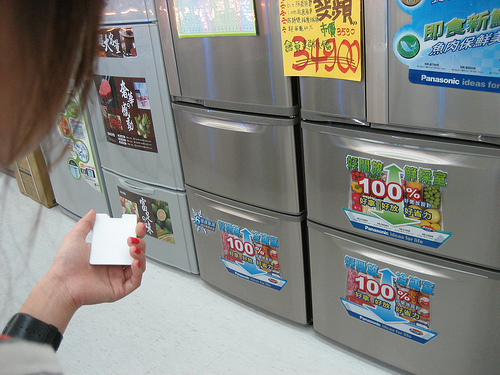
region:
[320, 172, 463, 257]
sign on the door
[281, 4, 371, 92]
red lettering on the sign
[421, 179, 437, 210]
grapes in the picture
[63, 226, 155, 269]
girl with phone in hand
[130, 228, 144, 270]
nail polish on fingernails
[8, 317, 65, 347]
black wrist band on wrist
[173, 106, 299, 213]
front of shelf is gray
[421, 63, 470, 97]
make of appliance on sign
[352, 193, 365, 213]
tomatoes on the advertisment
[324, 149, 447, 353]
two signs on each shelf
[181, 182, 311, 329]
a brushed aluminum refrigerator drawer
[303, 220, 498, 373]
a brushed aluminum refrigerator drawer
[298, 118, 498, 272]
a brushed aluminum refrigerator drawer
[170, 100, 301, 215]
a brushed aluminum refrigerator drawer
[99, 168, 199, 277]
a brushed aluminum refrigerator drawer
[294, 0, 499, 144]
a brushed aluminum refrigerator door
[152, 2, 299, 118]
a brushed aluminum refrigerator drawer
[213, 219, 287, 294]
a sticker advertisement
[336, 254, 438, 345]
a sticker advertisement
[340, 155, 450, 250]
a sticker advertisement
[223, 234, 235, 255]
The white number is outlined in red.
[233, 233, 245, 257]
The white number is outlined in red.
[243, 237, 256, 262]
The white number is outlined in red.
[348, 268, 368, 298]
The white number is outlined in red.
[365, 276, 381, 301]
The white number is outlined in red.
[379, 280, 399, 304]
The white number is outlined in red.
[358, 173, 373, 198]
The white number is outlined in red.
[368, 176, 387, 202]
The white number is outlined in red.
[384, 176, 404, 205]
The white number is outlined in red.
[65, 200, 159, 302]
The fingernails are painted red.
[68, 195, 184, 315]
hand of the girl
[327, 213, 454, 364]
a display in the box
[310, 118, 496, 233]
a display in the oven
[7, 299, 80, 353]
hand of the person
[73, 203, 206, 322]
a white paper in hand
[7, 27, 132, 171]
hairs of the girl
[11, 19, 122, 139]
part of the hairs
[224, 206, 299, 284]
a sticker to the machine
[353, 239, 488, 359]
a display of add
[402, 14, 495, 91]
a blue sticker in top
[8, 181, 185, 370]
a woman's hand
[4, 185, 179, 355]
a hand holding something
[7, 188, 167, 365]
a woman wearing a black band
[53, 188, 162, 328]
a hand with red nail polish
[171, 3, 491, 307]
silver appliances next to eachother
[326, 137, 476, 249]
a sign with 100% written on it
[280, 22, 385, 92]
the number 34900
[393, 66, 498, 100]
the name panasonic in white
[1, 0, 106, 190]
brown hair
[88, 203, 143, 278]
a white card holder